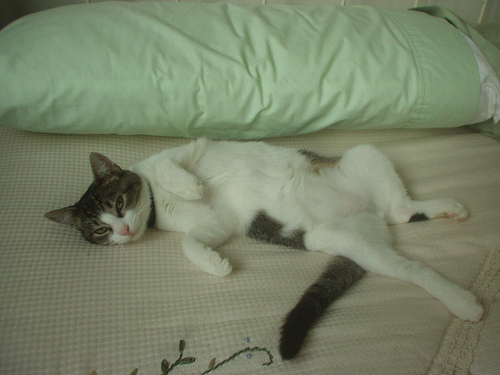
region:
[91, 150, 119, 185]
a cats ear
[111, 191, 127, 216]
a cats eye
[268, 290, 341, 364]
a cats tail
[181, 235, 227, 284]
the front right paw of a cat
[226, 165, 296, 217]
the belly of a cat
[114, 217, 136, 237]
the nose of a cat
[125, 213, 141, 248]
the mouth of a cat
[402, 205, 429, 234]
a black spot on a cat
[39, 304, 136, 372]
a pink and white blanket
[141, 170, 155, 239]
a cats collar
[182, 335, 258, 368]
green decorative stitch on sheet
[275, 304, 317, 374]
black tip of cat's tail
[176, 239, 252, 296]
cat's white paw on sheet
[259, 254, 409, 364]
long black cat's tail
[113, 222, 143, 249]
soft pink nose on cat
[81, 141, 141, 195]
brown ear on cat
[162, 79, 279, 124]
wrinkles in green pillow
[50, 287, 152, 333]
pattern on brown and white sheet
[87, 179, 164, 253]
beautiful doe shaped eyes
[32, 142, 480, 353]
large cat laying on bed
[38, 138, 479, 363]
a brown and white cat laying on the bed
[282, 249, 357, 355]
a brown tail laying on the bed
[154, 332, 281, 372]
embroidery on the comforter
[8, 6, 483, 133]
a green pillowcase covering the pillow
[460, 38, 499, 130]
the pillow sticking out from the end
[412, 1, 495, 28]
the wall next to the bed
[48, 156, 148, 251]
the head of the kitty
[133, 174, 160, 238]
the collar on the cat's neck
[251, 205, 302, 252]
a brown spot on the kitty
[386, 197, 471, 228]
a foot on the kitty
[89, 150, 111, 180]
a cats left ear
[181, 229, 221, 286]
a cats front right paw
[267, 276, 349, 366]
a cats black tail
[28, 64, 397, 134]
a green pillow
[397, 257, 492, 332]
a back right foot of a cat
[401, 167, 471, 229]
back left foot of a cat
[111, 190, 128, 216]
the eye of a cat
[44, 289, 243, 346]
a pink and white blanket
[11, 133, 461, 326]
grey and white cat is laying on bed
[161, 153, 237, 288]
cat has white feet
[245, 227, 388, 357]
cat has grey and black tail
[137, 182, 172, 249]
cat wearing black collar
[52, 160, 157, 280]
cat has green eyes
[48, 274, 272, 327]
bed spread has small checkered pattern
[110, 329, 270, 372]
part of the bedspread is embroidered with leaves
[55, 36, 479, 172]
light green pillow is behind cat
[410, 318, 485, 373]
decorative trim on bed spread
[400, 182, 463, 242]
cat has black spot on one foot